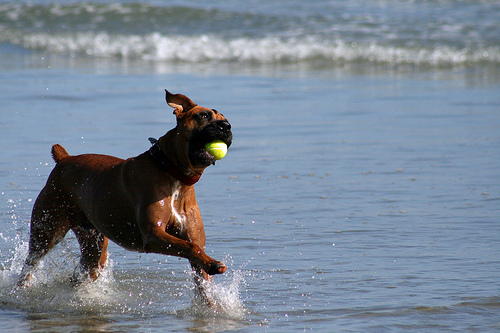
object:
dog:
[15, 88, 229, 309]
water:
[313, 138, 429, 239]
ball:
[204, 139, 228, 160]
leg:
[143, 229, 207, 263]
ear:
[164, 88, 202, 116]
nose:
[215, 119, 235, 131]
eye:
[194, 109, 212, 126]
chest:
[157, 184, 200, 235]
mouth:
[203, 135, 233, 164]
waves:
[20, 9, 500, 75]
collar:
[161, 147, 203, 186]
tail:
[51, 143, 67, 161]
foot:
[198, 256, 227, 277]